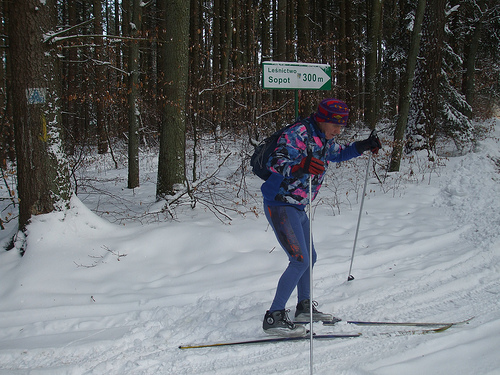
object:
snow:
[0, 115, 497, 375]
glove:
[291, 155, 326, 179]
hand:
[300, 155, 325, 176]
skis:
[291, 314, 479, 326]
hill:
[0, 153, 496, 375]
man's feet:
[264, 309, 308, 338]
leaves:
[62, 72, 140, 110]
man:
[250, 96, 383, 340]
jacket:
[260, 121, 364, 209]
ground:
[0, 121, 500, 375]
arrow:
[262, 65, 331, 89]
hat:
[314, 99, 349, 140]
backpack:
[250, 120, 314, 182]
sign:
[262, 61, 333, 90]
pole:
[307, 170, 312, 371]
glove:
[370, 129, 382, 155]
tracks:
[10, 301, 126, 350]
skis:
[177, 323, 455, 350]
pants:
[262, 202, 318, 314]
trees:
[3, 0, 252, 212]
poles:
[343, 127, 377, 281]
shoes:
[262, 309, 309, 338]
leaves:
[86, 155, 116, 167]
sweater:
[262, 115, 365, 212]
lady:
[249, 97, 382, 337]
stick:
[306, 174, 313, 374]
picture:
[0, 0, 500, 375]